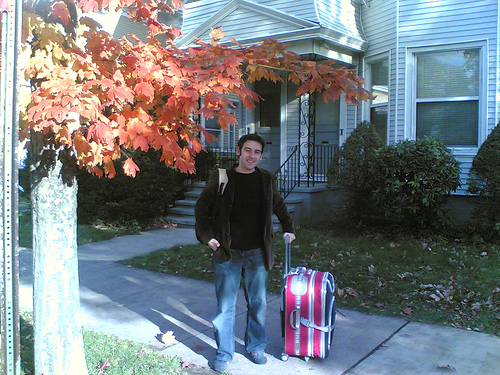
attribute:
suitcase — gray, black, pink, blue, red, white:
[281, 234, 337, 363]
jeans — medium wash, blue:
[210, 247, 272, 357]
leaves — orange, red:
[24, 0, 378, 179]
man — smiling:
[192, 134, 298, 373]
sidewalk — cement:
[17, 246, 499, 373]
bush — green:
[365, 137, 459, 216]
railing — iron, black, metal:
[272, 77, 340, 201]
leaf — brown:
[159, 328, 178, 348]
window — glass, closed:
[405, 39, 488, 152]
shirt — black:
[232, 167, 264, 249]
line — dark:
[336, 320, 414, 374]